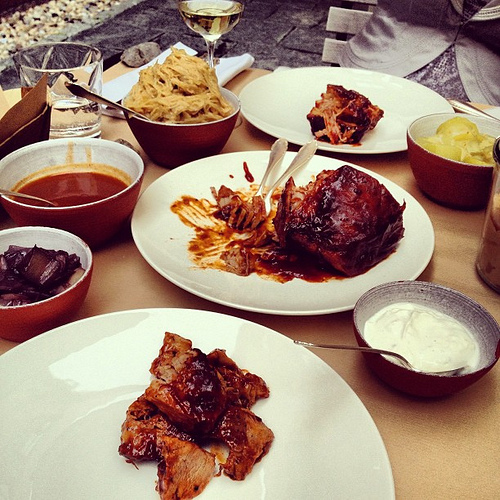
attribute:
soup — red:
[11, 143, 132, 207]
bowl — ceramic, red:
[0, 136, 145, 246]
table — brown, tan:
[3, 62, 498, 500]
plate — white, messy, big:
[132, 145, 433, 317]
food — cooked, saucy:
[274, 166, 407, 287]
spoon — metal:
[2, 187, 61, 208]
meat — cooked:
[119, 331, 276, 497]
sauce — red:
[170, 354, 226, 430]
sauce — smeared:
[174, 158, 343, 284]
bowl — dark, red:
[120, 86, 240, 166]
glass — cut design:
[14, 43, 102, 144]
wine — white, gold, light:
[180, 0, 245, 39]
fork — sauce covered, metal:
[229, 141, 320, 230]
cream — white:
[365, 302, 481, 374]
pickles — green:
[416, 118, 496, 168]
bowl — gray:
[353, 279, 499, 401]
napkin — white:
[102, 39, 256, 123]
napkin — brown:
[0, 74, 50, 146]